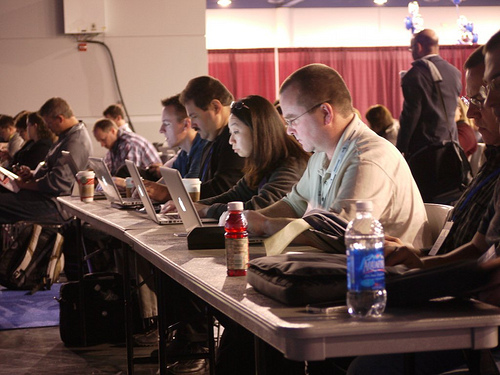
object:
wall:
[0, 0, 205, 162]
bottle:
[344, 199, 387, 319]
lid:
[76, 170, 96, 179]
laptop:
[158, 166, 271, 244]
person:
[218, 62, 432, 250]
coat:
[394, 55, 464, 154]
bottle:
[224, 201, 250, 277]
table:
[51, 195, 500, 375]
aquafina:
[346, 200, 388, 319]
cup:
[76, 168, 96, 202]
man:
[142, 75, 246, 203]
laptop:
[124, 158, 219, 225]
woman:
[158, 94, 313, 222]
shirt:
[95, 127, 163, 192]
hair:
[277, 62, 355, 119]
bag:
[246, 250, 494, 308]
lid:
[355, 200, 374, 213]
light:
[371, 0, 388, 5]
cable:
[79, 37, 136, 134]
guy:
[394, 27, 473, 202]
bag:
[55, 271, 143, 348]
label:
[346, 246, 386, 292]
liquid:
[225, 211, 250, 277]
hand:
[244, 210, 269, 237]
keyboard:
[248, 235, 270, 239]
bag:
[414, 63, 475, 191]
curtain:
[208, 45, 483, 127]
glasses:
[284, 99, 336, 128]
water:
[346, 218, 386, 317]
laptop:
[87, 157, 164, 210]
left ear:
[210, 99, 223, 115]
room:
[0, 0, 499, 374]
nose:
[190, 120, 197, 129]